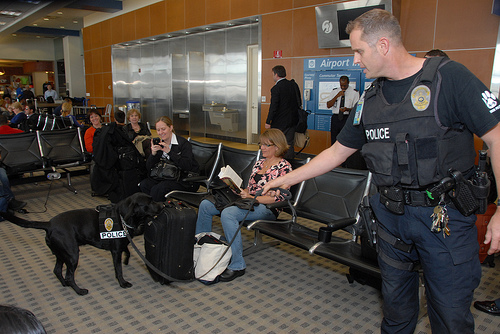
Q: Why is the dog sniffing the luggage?
A: The dog is looking for narcotics.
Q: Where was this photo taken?
A: Airport.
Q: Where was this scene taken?
A: Airport.